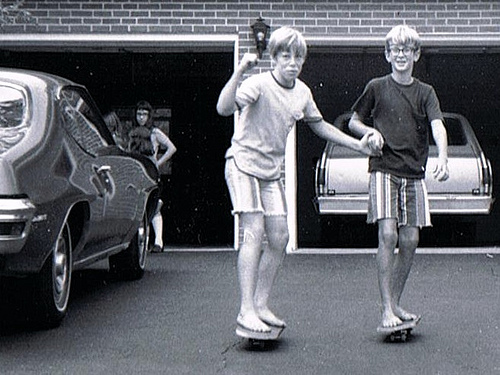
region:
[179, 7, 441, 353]
boys are riding skateboard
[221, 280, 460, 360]
the feet are bare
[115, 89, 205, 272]
the girl is watching the boys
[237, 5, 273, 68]
lamp on the wall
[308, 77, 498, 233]
car parked in garage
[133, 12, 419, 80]
the wall is bricked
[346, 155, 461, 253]
the short is stripes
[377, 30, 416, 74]
the boy is wearing eyeglasses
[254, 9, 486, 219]
boys are holding hands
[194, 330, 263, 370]
a crack on the ground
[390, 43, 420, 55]
a boy's eyeglasses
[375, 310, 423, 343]
part of a skateboard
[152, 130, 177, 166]
the arm of a woman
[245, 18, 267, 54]
a black outdoor light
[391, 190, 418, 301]
the leg of a boy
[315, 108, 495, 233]
the back of a car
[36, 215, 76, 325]
a car tire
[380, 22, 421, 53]
a boy's short hair cut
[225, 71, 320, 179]
a boy's short sleeve shirt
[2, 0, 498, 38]
part of a brick building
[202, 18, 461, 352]
Two boys riding skateboards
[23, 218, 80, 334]
A black round tire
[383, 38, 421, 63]
Boy is wearing glasses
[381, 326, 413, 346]
Wheels under the skateboard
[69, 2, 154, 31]
Bricks on the house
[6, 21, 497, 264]
Two open garages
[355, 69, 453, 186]
A dark t-shirt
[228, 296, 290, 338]
Two bare feet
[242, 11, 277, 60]
Light fixture on the house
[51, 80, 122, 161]
Window on side of a car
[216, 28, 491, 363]
Two boys holding hands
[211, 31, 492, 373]
Two boys on a skateboard.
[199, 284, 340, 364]
Skateboard on the ground.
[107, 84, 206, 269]
Girl in the background.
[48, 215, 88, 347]
Wheel on the vehicle.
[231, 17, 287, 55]
Light on the garage.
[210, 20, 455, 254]
Boys wearing shorts.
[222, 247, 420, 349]
Boys with bare feet.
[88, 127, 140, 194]
Door handle on the car.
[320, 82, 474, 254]
Car in a garage.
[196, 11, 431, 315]
two kids on skateboards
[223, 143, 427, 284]
kids have striped shorts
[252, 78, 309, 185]
left boy has white shirt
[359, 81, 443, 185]
white boy has dark shirt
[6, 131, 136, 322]
car next to boy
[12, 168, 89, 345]
car has black tires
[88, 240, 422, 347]
boys are on sidewalk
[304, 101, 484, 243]
car behind right boy in garage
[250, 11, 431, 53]
garage is made of brick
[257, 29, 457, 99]
both boys have blond hair